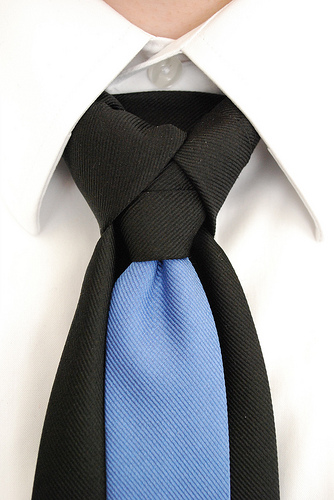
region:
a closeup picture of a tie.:
[54, 65, 310, 496]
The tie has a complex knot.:
[81, 110, 211, 258]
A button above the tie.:
[139, 39, 171, 94]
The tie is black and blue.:
[78, 145, 273, 476]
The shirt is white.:
[22, 76, 301, 107]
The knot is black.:
[78, 107, 225, 225]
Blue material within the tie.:
[118, 269, 243, 493]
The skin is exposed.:
[163, 32, 183, 38]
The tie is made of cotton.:
[86, 105, 225, 246]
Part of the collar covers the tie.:
[31, 77, 288, 215]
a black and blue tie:
[86, 92, 259, 421]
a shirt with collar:
[29, 49, 330, 260]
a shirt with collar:
[25, 101, 332, 450]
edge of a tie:
[219, 465, 235, 489]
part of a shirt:
[276, 425, 289, 448]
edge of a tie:
[216, 421, 234, 452]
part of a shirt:
[270, 420, 287, 448]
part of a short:
[268, 403, 288, 441]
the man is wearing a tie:
[0, 2, 308, 490]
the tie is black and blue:
[10, 102, 303, 490]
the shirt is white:
[47, 2, 327, 242]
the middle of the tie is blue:
[56, 244, 245, 487]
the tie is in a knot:
[35, 67, 277, 284]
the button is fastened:
[120, 24, 193, 86]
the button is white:
[129, 46, 194, 88]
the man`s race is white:
[108, 3, 225, 49]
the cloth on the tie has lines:
[45, 218, 283, 393]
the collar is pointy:
[3, 144, 332, 254]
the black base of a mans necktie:
[31, 91, 291, 498]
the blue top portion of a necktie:
[107, 254, 232, 498]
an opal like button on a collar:
[147, 54, 181, 88]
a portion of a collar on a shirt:
[0, 0, 154, 237]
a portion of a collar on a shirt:
[180, 1, 333, 237]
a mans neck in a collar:
[104, 0, 237, 41]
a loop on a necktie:
[114, 184, 203, 262]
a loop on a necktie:
[62, 96, 184, 235]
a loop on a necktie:
[176, 97, 264, 241]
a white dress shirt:
[0, 0, 333, 499]